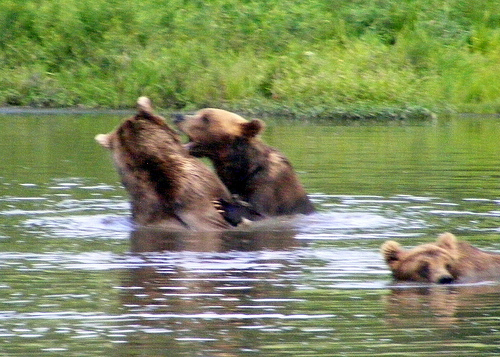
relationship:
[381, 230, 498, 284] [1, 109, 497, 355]
bear playing in water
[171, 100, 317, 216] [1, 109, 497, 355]
bear playing in water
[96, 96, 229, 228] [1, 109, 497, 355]
bear playing in water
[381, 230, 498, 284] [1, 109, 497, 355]
bear swimming in river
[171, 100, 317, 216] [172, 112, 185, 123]
bear has nose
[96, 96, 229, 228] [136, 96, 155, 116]
bear has ear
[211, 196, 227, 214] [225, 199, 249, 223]
claws on paw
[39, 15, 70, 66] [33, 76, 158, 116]
bush growing on bank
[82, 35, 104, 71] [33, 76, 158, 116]
bush growing on bank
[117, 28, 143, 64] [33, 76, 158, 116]
bush growing on bank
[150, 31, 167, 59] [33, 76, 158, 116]
bush growing on bank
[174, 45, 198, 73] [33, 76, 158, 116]
bush growing on bank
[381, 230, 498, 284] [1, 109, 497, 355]
bear under water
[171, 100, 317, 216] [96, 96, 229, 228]
bear attempting to bite bear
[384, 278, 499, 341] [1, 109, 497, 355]
reflectio i water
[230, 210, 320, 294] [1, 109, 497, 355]
reflectio i water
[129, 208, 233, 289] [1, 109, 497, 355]
reflectio i water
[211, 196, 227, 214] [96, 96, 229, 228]
claws of bear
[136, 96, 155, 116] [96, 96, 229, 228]
ear of bear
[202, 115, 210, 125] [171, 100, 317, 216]
ee of bear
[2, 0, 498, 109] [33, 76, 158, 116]
vegetatio on bank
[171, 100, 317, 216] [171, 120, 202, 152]
bear with mouth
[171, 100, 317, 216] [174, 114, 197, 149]
bear has opened bear's mouth